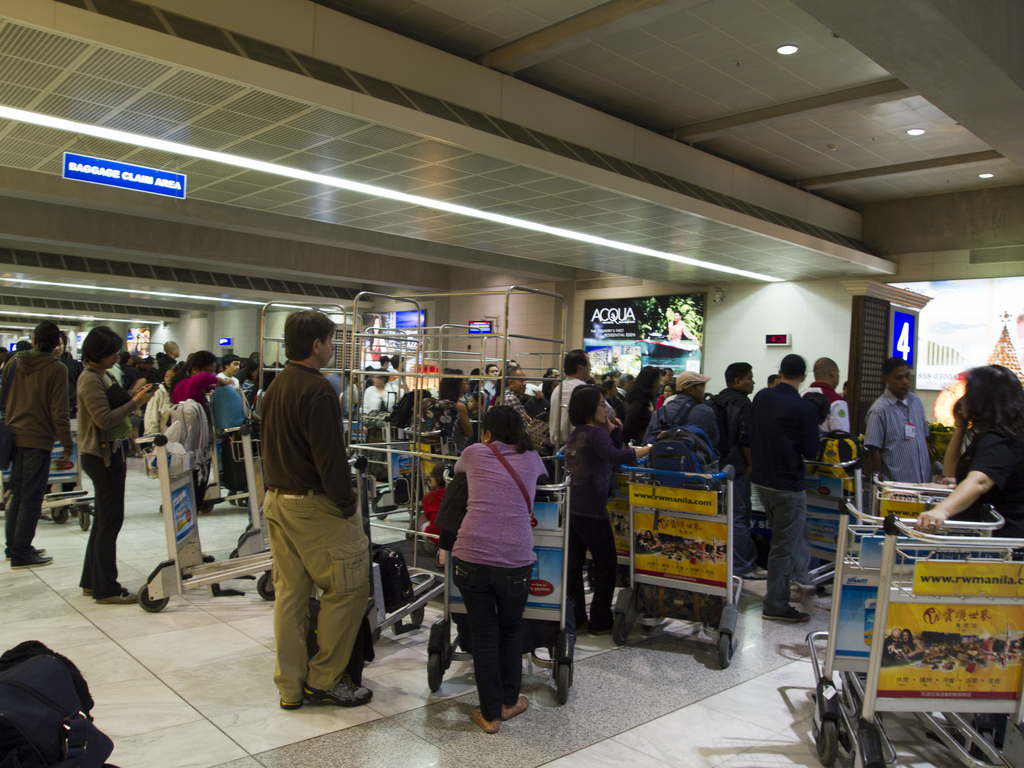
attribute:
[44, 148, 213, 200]
sign — blue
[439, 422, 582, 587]
top — pink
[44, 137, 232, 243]
sign — blue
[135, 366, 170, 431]
phone — cell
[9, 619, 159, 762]
bag — blue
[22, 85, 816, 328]
light — white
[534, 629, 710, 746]
tile — grey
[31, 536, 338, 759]
tile — white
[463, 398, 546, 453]
hair — black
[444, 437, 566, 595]
shirt — pink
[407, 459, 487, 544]
bag — red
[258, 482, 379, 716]
pants — man's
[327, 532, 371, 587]
pockets — on the sides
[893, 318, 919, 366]
4 — written in white